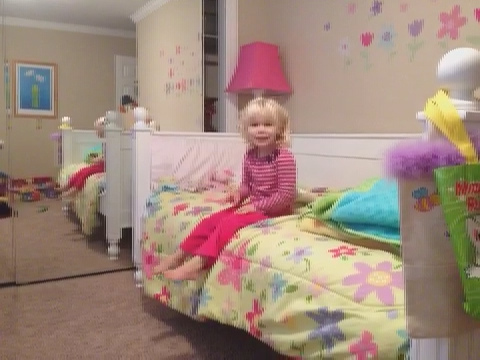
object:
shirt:
[235, 147, 298, 214]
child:
[150, 96, 295, 282]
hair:
[237, 97, 293, 148]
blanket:
[294, 176, 400, 257]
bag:
[421, 88, 479, 318]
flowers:
[322, 0, 479, 69]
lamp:
[222, 41, 292, 100]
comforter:
[137, 176, 411, 360]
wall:
[267, 0, 480, 134]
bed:
[130, 45, 480, 360]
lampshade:
[223, 41, 291, 96]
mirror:
[0, 0, 203, 285]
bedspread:
[136, 188, 409, 360]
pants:
[178, 201, 292, 269]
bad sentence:
[100, 174, 149, 215]